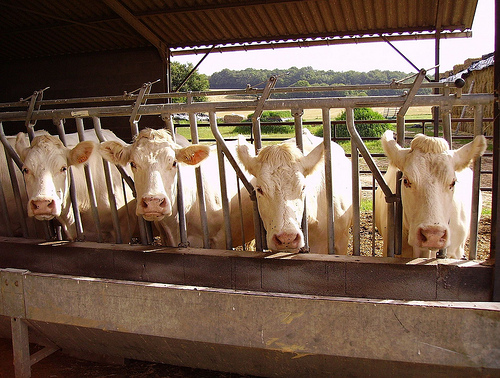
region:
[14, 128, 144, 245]
cow has head in trough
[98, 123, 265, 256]
cow has head in trough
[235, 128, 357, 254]
cow has head in trough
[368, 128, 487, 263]
cow has head in trough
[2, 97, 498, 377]
no food is in the trough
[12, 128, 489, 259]
four cows wait to be fed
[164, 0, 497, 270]
sun is shining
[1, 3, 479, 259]
four cows under a roof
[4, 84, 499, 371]
trough is made of metal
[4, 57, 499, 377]
trough has holes for animals to put their heads through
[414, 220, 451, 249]
pink nose on white cow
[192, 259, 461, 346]
concrete cattle feeding troth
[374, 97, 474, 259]
white cows head in metal fence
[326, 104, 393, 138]
green hay piled up behind cows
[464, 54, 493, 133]
brown hay piled up behind cows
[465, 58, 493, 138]
brown hay piled up with black tarp on top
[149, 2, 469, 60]
metal awning over white cows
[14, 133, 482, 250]
four white cows in metal fence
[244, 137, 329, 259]
white cow getting ready to eat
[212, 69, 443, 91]
green forest in the background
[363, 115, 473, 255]
head of white cow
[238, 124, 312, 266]
head of white cow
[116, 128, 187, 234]
head of white cow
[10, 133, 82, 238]
head of white cow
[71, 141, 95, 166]
ear of the cow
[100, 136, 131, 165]
ear of the cow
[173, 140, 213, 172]
ear of the cow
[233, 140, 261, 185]
ear of the cow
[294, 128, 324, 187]
ear of the cow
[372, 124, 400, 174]
ear of the cow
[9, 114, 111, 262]
the cow is white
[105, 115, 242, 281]
the cow is white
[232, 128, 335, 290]
the cow is white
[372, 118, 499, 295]
the cow is white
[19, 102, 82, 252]
the cow is looking at the camera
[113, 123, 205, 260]
the cow is looking at the camera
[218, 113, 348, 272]
the cow is looking at the camera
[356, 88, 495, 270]
the cow is looking at the camera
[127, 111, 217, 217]
the cow is looking at the camera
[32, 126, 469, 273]
four cattle in barn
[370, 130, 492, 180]
cow has white ears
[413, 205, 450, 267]
cow has pink nose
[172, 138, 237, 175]
cow's left ear is tagged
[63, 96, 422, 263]
gates have grey bars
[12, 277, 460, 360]
grey fence under grey bars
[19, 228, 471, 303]
red bricks under cows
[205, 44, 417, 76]
sky is bright and grey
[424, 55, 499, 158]
brown building behind barn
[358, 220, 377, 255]
brown dirt behind cows